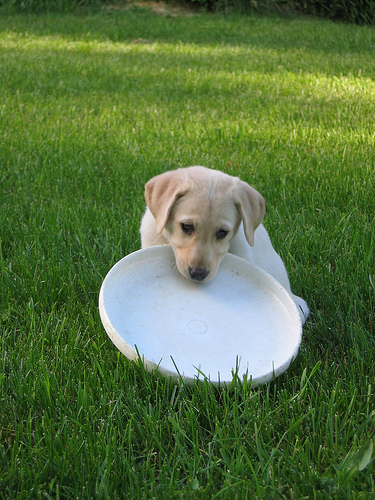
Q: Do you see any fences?
A: No, there are no fences.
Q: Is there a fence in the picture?
A: No, there are no fences.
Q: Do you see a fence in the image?
A: No, there are no fences.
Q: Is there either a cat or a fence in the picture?
A: No, there are no fences or cats.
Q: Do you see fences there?
A: No, there are no fences.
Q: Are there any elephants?
A: No, there are no elephants.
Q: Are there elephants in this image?
A: No, there are no elephants.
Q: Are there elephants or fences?
A: No, there are no elephants or fences.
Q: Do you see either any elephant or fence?
A: No, there are no elephants or fences.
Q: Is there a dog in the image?
A: Yes, there is a dog.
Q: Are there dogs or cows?
A: Yes, there is a dog.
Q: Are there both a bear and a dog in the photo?
A: No, there is a dog but no bears.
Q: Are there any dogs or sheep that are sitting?
A: Yes, the dog is sitting.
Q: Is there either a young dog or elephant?
A: Yes, there is a young dog.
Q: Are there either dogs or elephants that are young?
A: Yes, the dog is young.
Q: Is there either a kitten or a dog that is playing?
A: Yes, the dog is playing.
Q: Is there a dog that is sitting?
A: Yes, there is a dog that is sitting.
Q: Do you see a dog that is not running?
A: Yes, there is a dog that is sitting .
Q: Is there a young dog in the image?
A: Yes, there is a young dog.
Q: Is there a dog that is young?
A: Yes, there is a dog that is young.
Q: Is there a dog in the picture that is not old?
A: Yes, there is an young dog.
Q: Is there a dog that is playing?
A: Yes, there is a dog that is playing.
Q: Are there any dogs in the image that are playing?
A: Yes, there is a dog that is playing.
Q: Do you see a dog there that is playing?
A: Yes, there is a dog that is playing.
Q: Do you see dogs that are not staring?
A: Yes, there is a dog that is playing .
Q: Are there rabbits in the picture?
A: No, there are no rabbits.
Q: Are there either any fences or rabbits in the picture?
A: No, there are no rabbits or fences.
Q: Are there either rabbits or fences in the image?
A: No, there are no rabbits or fences.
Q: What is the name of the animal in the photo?
A: The animal is a dog.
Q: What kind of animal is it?
A: The animal is a dog.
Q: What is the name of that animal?
A: This is a dog.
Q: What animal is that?
A: This is a dog.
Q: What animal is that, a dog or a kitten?
A: This is a dog.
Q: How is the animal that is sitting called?
A: The animal is a dog.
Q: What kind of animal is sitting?
A: The animal is a dog.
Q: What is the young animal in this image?
A: The animal is a dog.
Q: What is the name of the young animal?
A: The animal is a dog.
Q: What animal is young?
A: The animal is a dog.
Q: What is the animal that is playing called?
A: The animal is a dog.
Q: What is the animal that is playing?
A: The animal is a dog.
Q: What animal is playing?
A: The animal is a dog.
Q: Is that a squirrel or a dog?
A: That is a dog.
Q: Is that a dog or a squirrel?
A: That is a dog.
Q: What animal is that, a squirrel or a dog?
A: That is a dog.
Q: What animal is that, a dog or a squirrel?
A: That is a dog.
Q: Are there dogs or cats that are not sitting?
A: No, there is a dog but it is sitting.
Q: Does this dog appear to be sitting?
A: Yes, the dog is sitting.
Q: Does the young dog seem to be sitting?
A: Yes, the dog is sitting.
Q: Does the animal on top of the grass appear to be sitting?
A: Yes, the dog is sitting.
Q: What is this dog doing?
A: The dog is sitting.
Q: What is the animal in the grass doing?
A: The dog is sitting.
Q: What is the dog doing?
A: The dog is sitting.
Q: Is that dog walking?
A: No, the dog is sitting.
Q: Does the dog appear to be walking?
A: No, the dog is sitting.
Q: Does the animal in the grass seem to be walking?
A: No, the dog is sitting.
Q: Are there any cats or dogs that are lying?
A: No, there is a dog but it is sitting.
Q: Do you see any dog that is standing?
A: No, there is a dog but it is sitting.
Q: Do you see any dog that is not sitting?
A: No, there is a dog but it is sitting.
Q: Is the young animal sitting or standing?
A: The dog is sitting.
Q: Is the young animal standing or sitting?
A: The dog is sitting.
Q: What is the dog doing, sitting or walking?
A: The dog is sitting.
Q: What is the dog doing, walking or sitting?
A: The dog is sitting.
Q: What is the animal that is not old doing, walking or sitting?
A: The dog is sitting.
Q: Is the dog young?
A: Yes, the dog is young.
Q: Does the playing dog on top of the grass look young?
A: Yes, the dog is young.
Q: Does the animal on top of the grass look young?
A: Yes, the dog is young.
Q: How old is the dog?
A: The dog is young.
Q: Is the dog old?
A: No, the dog is young.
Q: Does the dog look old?
A: No, the dog is young.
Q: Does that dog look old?
A: No, the dog is young.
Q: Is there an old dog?
A: No, there is a dog but it is young.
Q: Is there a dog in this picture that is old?
A: No, there is a dog but it is young.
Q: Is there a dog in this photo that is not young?
A: No, there is a dog but it is young.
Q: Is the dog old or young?
A: The dog is young.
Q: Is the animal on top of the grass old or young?
A: The dog is young.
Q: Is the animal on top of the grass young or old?
A: The dog is young.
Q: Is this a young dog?
A: Yes, this is a young dog.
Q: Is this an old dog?
A: No, this is a young dog.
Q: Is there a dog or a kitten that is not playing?
A: No, there is a dog but it is playing.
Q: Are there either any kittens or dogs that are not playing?
A: No, there is a dog but it is playing.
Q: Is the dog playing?
A: Yes, the dog is playing.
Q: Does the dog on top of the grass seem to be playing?
A: Yes, the dog is playing.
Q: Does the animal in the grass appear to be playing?
A: Yes, the dog is playing.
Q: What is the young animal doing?
A: The dog is playing.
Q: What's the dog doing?
A: The dog is playing.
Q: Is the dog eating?
A: No, the dog is playing.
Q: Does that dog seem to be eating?
A: No, the dog is playing.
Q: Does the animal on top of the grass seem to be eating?
A: No, the dog is playing.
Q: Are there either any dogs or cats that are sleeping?
A: No, there is a dog but it is playing.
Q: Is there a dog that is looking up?
A: No, there is a dog but it is playing.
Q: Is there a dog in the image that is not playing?
A: No, there is a dog but it is playing.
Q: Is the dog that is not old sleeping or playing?
A: The dog is playing.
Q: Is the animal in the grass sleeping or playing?
A: The dog is playing.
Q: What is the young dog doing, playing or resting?
A: The dog is playing.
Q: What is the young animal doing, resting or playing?
A: The dog is playing.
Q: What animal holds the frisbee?
A: The dog holds the frisbee.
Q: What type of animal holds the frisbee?
A: The animal is a dog.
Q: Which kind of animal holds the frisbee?
A: The animal is a dog.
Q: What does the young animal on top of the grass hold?
A: The dog holds the frisbee.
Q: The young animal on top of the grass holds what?
A: The dog holds the frisbee.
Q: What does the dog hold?
A: The dog holds the frisbee.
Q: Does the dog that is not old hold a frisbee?
A: Yes, the dog holds a frisbee.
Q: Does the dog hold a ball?
A: No, the dog holds a frisbee.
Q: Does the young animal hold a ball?
A: No, the dog holds a frisbee.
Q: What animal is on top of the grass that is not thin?
A: The dog is on top of the grass.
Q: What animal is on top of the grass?
A: The dog is on top of the grass.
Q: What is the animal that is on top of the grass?
A: The animal is a dog.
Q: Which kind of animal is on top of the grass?
A: The animal is a dog.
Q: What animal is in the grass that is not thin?
A: The dog is in the grass.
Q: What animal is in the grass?
A: The animal is a dog.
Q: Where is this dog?
A: The dog is in the grass.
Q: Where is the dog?
A: The dog is in the grass.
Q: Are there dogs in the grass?
A: Yes, there is a dog in the grass.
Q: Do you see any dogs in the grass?
A: Yes, there is a dog in the grass.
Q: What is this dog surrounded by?
A: The dog is surrounded by the grass.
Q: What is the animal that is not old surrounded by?
A: The dog is surrounded by the grass.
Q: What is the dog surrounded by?
A: The dog is surrounded by the grass.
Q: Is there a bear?
A: No, there are no bears.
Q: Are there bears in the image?
A: No, there are no bears.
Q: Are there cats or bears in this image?
A: No, there are no bears or cats.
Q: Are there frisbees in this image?
A: Yes, there is a frisbee.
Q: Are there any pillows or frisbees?
A: Yes, there is a frisbee.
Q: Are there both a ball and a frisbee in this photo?
A: No, there is a frisbee but no balls.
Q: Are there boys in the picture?
A: No, there are no boys.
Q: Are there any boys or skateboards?
A: No, there are no boys or skateboards.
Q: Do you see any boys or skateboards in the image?
A: No, there are no boys or skateboards.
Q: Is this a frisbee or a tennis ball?
A: This is a frisbee.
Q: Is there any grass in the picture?
A: Yes, there is grass.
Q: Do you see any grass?
A: Yes, there is grass.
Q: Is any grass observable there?
A: Yes, there is grass.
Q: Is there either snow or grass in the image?
A: Yes, there is grass.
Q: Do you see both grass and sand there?
A: No, there is grass but no sand.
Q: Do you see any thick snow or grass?
A: Yes, there is thick grass.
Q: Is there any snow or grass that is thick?
A: Yes, the grass is thick.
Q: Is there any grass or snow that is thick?
A: Yes, the grass is thick.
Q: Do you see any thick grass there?
A: Yes, there is thick grass.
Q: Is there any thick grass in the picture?
A: Yes, there is thick grass.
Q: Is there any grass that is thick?
A: Yes, there is grass that is thick.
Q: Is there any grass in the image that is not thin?
A: Yes, there is thick grass.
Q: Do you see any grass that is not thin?
A: Yes, there is thick grass.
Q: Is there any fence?
A: No, there are no fences.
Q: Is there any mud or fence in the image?
A: No, there are no fences or mud.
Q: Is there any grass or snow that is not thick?
A: No, there is grass but it is thick.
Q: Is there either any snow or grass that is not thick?
A: No, there is grass but it is thick.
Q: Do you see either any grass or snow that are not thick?
A: No, there is grass but it is thick.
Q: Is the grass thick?
A: Yes, the grass is thick.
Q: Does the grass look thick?
A: Yes, the grass is thick.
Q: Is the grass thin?
A: No, the grass is thick.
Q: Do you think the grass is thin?
A: No, the grass is thick.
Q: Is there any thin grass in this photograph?
A: No, there is grass but it is thick.